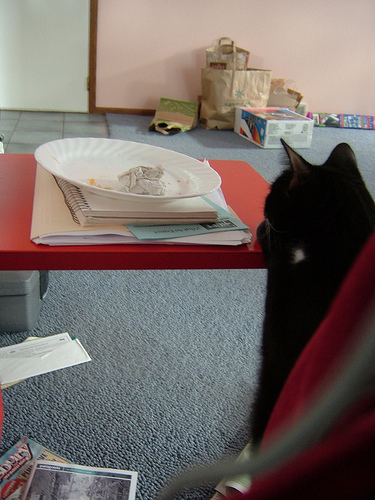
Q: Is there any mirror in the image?
A: No, there are no mirrors.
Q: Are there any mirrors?
A: No, there are no mirrors.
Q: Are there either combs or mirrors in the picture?
A: No, there are no mirrors or combs.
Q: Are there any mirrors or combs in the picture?
A: No, there are no mirrors or combs.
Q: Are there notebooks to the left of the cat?
A: Yes, there is a notebook to the left of the cat.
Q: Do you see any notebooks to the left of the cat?
A: Yes, there is a notebook to the left of the cat.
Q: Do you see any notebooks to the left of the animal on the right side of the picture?
A: Yes, there is a notebook to the left of the cat.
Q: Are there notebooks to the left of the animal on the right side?
A: Yes, there is a notebook to the left of the cat.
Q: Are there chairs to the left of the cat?
A: No, there is a notebook to the left of the cat.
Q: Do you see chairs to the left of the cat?
A: No, there is a notebook to the left of the cat.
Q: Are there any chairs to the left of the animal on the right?
A: No, there is a notebook to the left of the cat.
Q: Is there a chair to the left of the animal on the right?
A: No, there is a notebook to the left of the cat.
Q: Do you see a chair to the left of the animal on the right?
A: No, there is a notebook to the left of the cat.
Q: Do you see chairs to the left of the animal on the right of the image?
A: No, there is a notebook to the left of the cat.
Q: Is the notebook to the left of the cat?
A: Yes, the notebook is to the left of the cat.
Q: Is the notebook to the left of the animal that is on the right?
A: Yes, the notebook is to the left of the cat.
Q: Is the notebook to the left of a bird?
A: No, the notebook is to the left of the cat.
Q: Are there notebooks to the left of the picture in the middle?
A: Yes, there is a notebook to the left of the picture.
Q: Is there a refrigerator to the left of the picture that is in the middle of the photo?
A: No, there is a notebook to the left of the picture.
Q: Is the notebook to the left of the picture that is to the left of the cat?
A: Yes, the notebook is to the left of the picture.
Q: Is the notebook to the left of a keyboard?
A: No, the notebook is to the left of the picture.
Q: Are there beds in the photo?
A: No, there are no beds.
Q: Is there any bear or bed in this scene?
A: No, there are no beds or bears.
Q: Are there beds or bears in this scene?
A: No, there are no beds or bears.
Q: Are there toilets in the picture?
A: No, there are no toilets.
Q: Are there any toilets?
A: No, there are no toilets.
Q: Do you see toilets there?
A: No, there are no toilets.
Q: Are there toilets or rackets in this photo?
A: No, there are no toilets or rackets.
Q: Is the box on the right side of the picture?
A: Yes, the box is on the right of the image.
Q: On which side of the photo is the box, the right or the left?
A: The box is on the right of the image.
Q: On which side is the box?
A: The box is on the right of the image.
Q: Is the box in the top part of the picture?
A: Yes, the box is in the top of the image.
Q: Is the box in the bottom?
A: No, the box is in the top of the image.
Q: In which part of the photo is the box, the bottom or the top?
A: The box is in the top of the image.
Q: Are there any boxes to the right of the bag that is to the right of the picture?
A: Yes, there is a box to the right of the bag.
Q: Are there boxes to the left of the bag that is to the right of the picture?
A: No, the box is to the right of the bag.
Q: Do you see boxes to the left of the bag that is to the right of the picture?
A: No, the box is to the right of the bag.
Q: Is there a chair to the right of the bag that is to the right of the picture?
A: No, there is a box to the right of the bag.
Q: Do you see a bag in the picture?
A: Yes, there is a bag.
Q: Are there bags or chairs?
A: Yes, there is a bag.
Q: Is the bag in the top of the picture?
A: Yes, the bag is in the top of the image.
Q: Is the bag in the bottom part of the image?
A: No, the bag is in the top of the image.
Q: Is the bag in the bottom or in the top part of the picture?
A: The bag is in the top of the image.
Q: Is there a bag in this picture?
A: Yes, there is a bag.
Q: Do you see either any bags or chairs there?
A: Yes, there is a bag.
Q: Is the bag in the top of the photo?
A: Yes, the bag is in the top of the image.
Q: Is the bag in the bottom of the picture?
A: No, the bag is in the top of the image.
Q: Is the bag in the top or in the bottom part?
A: The bag is in the top of the image.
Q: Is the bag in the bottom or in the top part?
A: The bag is in the top of the image.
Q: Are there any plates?
A: Yes, there is a plate.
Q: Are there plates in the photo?
A: Yes, there is a plate.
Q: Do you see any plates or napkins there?
A: Yes, there is a plate.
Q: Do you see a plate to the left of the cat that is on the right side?
A: Yes, there is a plate to the left of the cat.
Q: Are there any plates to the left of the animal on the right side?
A: Yes, there is a plate to the left of the cat.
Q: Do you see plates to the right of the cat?
A: No, the plate is to the left of the cat.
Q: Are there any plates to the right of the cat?
A: No, the plate is to the left of the cat.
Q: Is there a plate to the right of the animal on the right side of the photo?
A: No, the plate is to the left of the cat.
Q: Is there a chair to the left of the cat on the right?
A: No, there is a plate to the left of the cat.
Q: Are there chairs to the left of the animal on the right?
A: No, there is a plate to the left of the cat.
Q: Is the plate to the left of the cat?
A: Yes, the plate is to the left of the cat.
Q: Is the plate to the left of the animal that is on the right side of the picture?
A: Yes, the plate is to the left of the cat.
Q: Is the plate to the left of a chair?
A: No, the plate is to the left of the cat.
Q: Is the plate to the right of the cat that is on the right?
A: No, the plate is to the left of the cat.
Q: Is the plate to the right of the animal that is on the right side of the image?
A: No, the plate is to the left of the cat.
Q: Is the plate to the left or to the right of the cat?
A: The plate is to the left of the cat.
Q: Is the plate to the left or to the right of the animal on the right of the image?
A: The plate is to the left of the cat.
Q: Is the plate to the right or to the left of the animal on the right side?
A: The plate is to the left of the cat.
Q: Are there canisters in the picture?
A: No, there are no canisters.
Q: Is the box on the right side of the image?
A: Yes, the box is on the right of the image.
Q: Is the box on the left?
A: No, the box is on the right of the image.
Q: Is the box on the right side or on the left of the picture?
A: The box is on the right of the image.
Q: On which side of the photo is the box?
A: The box is on the right of the image.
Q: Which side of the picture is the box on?
A: The box is on the right of the image.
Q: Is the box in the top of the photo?
A: Yes, the box is in the top of the image.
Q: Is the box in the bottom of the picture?
A: No, the box is in the top of the image.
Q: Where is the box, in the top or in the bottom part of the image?
A: The box is in the top of the image.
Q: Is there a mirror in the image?
A: No, there are no mirrors.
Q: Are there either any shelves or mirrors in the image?
A: No, there are no mirrors or shelves.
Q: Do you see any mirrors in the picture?
A: No, there are no mirrors.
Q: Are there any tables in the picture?
A: Yes, there is a table.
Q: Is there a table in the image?
A: Yes, there is a table.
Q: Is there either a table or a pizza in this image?
A: Yes, there is a table.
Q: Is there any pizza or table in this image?
A: Yes, there is a table.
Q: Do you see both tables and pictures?
A: Yes, there are both a table and a picture.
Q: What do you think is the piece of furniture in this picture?
A: The piece of furniture is a table.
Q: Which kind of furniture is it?
A: The piece of furniture is a table.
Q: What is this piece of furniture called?
A: This is a table.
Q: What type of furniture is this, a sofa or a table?
A: This is a table.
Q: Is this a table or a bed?
A: This is a table.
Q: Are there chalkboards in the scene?
A: No, there are no chalkboards.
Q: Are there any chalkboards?
A: No, there are no chalkboards.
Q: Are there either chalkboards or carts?
A: No, there are no chalkboards or carts.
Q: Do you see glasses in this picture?
A: No, there are no glasses.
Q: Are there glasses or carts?
A: No, there are no glasses or carts.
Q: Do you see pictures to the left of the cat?
A: Yes, there is a picture to the left of the cat.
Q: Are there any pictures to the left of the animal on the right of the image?
A: Yes, there is a picture to the left of the cat.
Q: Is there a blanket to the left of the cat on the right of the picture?
A: No, there is a picture to the left of the cat.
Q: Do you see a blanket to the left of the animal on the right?
A: No, there is a picture to the left of the cat.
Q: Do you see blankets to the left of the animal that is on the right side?
A: No, there is a picture to the left of the cat.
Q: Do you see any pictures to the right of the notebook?
A: Yes, there is a picture to the right of the notebook.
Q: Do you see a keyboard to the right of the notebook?
A: No, there is a picture to the right of the notebook.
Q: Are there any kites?
A: No, there are no kites.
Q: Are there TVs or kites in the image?
A: No, there are no kites or tvs.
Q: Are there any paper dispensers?
A: No, there are no paper dispensers.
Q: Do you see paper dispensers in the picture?
A: No, there are no paper dispensers.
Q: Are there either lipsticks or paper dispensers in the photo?
A: No, there are no paper dispensers or lipsticks.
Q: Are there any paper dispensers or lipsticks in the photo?
A: No, there are no paper dispensers or lipsticks.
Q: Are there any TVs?
A: No, there are no tvs.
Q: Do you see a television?
A: No, there are no televisions.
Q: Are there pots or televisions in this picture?
A: No, there are no televisions or pots.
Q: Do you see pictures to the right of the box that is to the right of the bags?
A: Yes, there is a picture to the right of the box.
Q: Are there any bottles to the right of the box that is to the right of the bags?
A: No, there is a picture to the right of the box.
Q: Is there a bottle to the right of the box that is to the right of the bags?
A: No, there is a picture to the right of the box.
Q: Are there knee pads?
A: No, there are no knee pads.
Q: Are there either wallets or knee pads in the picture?
A: No, there are no knee pads or wallets.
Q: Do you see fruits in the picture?
A: No, there are no fruits.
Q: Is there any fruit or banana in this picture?
A: No, there are no fruits or bananas.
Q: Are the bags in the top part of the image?
A: Yes, the bags are in the top of the image.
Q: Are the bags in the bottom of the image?
A: No, the bags are in the top of the image.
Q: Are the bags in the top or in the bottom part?
A: The bags are in the top of the image.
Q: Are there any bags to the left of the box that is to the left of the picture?
A: Yes, there are bags to the left of the box.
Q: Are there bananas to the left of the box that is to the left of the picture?
A: No, there are bags to the left of the box.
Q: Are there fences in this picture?
A: No, there are no fences.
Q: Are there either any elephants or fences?
A: No, there are no fences or elephants.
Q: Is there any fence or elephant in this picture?
A: No, there are no fences or elephants.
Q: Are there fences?
A: No, there are no fences.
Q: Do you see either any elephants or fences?
A: No, there are no fences or elephants.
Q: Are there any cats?
A: Yes, there is a cat.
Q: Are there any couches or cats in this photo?
A: Yes, there is a cat.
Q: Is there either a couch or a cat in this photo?
A: Yes, there is a cat.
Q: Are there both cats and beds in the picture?
A: No, there is a cat but no beds.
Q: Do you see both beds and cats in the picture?
A: No, there is a cat but no beds.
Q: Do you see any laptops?
A: No, there are no laptops.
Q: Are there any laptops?
A: No, there are no laptops.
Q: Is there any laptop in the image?
A: No, there are no laptops.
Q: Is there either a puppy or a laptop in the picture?
A: No, there are no laptops or puppies.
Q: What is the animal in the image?
A: The animal is a cat.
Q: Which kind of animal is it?
A: The animal is a cat.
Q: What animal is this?
A: This is a cat.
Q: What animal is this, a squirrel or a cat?
A: This is a cat.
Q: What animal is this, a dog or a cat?
A: This is a cat.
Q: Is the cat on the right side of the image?
A: Yes, the cat is on the right of the image.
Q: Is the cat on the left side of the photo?
A: No, the cat is on the right of the image.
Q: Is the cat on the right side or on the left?
A: The cat is on the right of the image.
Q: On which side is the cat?
A: The cat is on the right of the image.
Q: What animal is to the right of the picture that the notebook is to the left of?
A: The animal is a cat.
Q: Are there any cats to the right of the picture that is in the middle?
A: Yes, there is a cat to the right of the picture.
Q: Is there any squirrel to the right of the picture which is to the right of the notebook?
A: No, there is a cat to the right of the picture.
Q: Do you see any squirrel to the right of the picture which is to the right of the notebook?
A: No, there is a cat to the right of the picture.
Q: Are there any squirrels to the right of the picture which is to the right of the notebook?
A: No, there is a cat to the right of the picture.